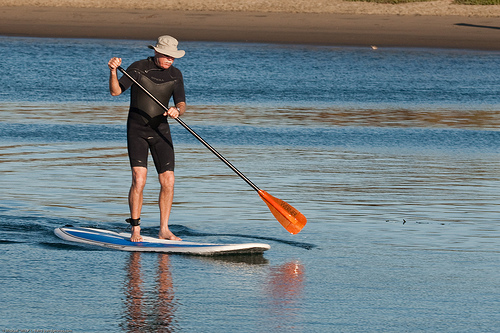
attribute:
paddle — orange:
[178, 130, 311, 240]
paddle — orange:
[197, 138, 350, 265]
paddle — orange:
[107, 60, 306, 238]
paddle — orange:
[158, 117, 345, 222]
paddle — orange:
[196, 116, 357, 248]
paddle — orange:
[252, 180, 314, 242]